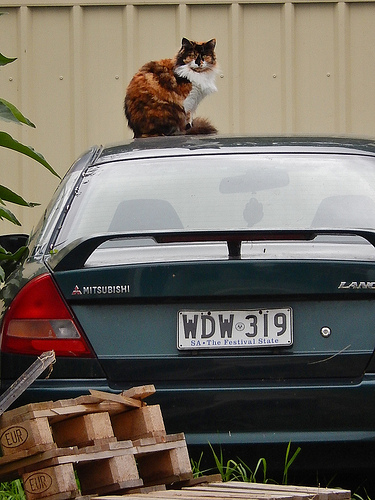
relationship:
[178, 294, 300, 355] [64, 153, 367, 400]
license plate on car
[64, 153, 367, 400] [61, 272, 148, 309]
car has logo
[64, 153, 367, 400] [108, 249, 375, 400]
car has trunk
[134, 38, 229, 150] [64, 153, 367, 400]
cat on car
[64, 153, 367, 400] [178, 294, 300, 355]
car has license plate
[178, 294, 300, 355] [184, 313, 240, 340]
license plate has letters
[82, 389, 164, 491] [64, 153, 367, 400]
wood beside car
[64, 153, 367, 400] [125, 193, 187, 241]
car has seat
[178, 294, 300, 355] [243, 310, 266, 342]
license plate has 3